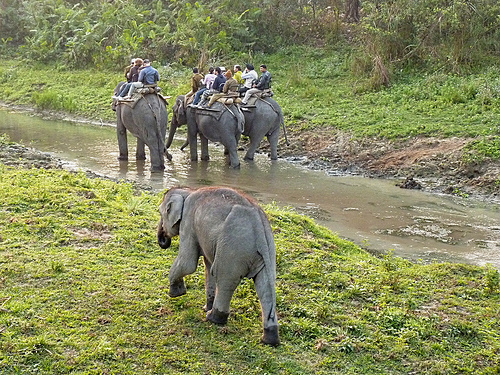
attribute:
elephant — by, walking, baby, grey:
[137, 174, 291, 320]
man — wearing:
[117, 44, 154, 99]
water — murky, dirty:
[342, 181, 450, 224]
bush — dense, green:
[35, 27, 186, 78]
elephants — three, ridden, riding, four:
[77, 79, 302, 180]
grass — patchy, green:
[47, 210, 109, 264]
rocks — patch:
[352, 175, 462, 244]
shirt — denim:
[136, 67, 168, 90]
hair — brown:
[184, 60, 208, 86]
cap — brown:
[255, 50, 270, 74]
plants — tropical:
[25, 212, 73, 287]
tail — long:
[262, 260, 289, 319]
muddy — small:
[348, 167, 476, 324]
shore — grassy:
[6, 96, 79, 152]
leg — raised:
[171, 245, 206, 295]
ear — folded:
[123, 193, 197, 266]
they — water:
[48, 125, 82, 153]